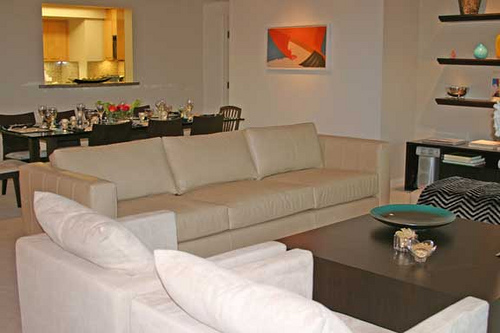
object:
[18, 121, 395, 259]
sofa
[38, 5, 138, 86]
window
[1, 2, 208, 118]
wall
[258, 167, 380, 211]
cushion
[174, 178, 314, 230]
cushion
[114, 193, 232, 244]
cushion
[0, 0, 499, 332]
room